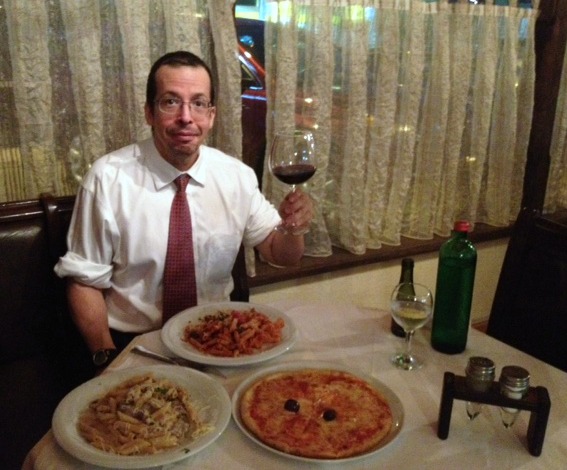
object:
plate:
[157, 296, 299, 368]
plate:
[228, 359, 408, 463]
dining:
[53, 296, 401, 469]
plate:
[54, 362, 235, 465]